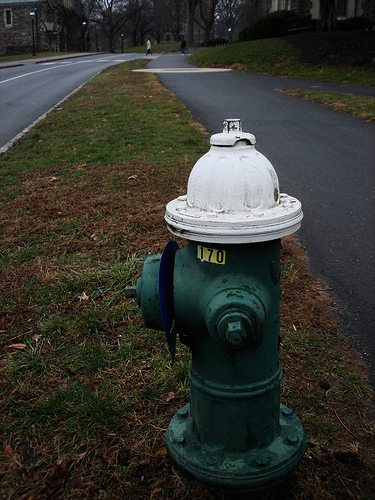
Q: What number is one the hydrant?
A: 170.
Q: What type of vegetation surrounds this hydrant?
A: Grass.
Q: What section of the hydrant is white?
A: The top.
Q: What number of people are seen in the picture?
A: 2.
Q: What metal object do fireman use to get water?
A: Hydrant.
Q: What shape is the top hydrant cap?
A: Circle.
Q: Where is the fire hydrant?
A: Outside by the road.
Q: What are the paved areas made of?
A: Concrete.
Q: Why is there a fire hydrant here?
A: In case of a fire.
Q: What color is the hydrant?
A: Green and white.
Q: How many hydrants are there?
A: One.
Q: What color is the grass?
A: Green and brown.